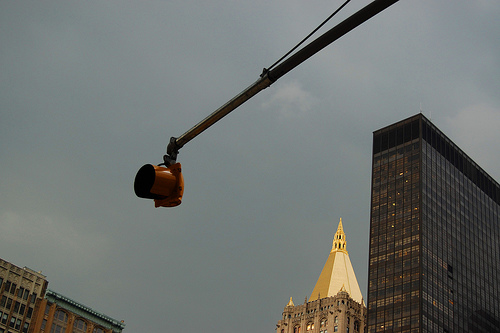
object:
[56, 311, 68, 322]
window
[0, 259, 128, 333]
building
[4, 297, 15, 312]
window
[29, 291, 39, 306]
window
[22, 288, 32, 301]
window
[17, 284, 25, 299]
window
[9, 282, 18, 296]
window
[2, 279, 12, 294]
window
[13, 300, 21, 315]
window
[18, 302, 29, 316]
window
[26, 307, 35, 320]
window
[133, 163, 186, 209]
casing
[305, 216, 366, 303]
golden pyramid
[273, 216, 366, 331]
sky scraper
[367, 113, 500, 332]
building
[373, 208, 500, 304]
many window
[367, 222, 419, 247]
windows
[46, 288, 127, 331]
green top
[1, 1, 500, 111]
sky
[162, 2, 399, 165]
metal arm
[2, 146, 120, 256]
gray clouds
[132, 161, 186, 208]
light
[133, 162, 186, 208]
cone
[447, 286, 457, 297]
small speck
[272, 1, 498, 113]
clouds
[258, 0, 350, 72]
cord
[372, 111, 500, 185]
top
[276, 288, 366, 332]
building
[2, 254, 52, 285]
roof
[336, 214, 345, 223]
point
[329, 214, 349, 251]
roof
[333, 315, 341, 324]
window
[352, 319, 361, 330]
window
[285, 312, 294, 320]
window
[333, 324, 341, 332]
window